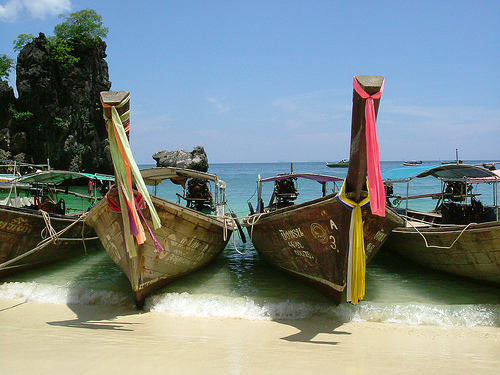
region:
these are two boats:
[120, 178, 383, 285]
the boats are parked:
[103, 155, 393, 301]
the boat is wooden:
[293, 212, 325, 255]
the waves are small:
[223, 287, 270, 325]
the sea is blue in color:
[228, 165, 250, 184]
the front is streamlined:
[318, 209, 375, 290]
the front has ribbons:
[345, 202, 382, 260]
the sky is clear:
[221, 2, 298, 70]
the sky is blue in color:
[241, 13, 316, 70]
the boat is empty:
[145, 185, 194, 222]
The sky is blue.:
[188, 10, 303, 75]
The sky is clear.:
[180, 8, 311, 66]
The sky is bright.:
[169, 6, 319, 63]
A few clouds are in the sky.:
[182, 59, 312, 124]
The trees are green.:
[47, 7, 113, 61]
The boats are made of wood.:
[1, 155, 498, 308]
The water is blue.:
[227, 166, 250, 192]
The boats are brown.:
[1, 150, 498, 312]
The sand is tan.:
[175, 332, 283, 372]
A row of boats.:
[1, 152, 497, 316]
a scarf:
[338, 71, 436, 211]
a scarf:
[342, 51, 396, 193]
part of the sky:
[255, 19, 305, 76]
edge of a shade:
[285, 332, 316, 357]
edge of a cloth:
[344, 291, 365, 310]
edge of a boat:
[316, 209, 353, 301]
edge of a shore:
[298, 315, 360, 357]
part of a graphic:
[274, 227, 323, 259]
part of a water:
[231, 254, 269, 286]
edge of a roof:
[281, 169, 303, 182]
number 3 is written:
[333, 233, 341, 251]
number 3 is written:
[332, 227, 343, 257]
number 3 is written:
[327, 231, 338, 249]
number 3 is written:
[324, 236, 337, 252]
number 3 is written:
[327, 235, 335, 245]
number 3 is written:
[327, 238, 341, 260]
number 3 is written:
[333, 235, 345, 263]